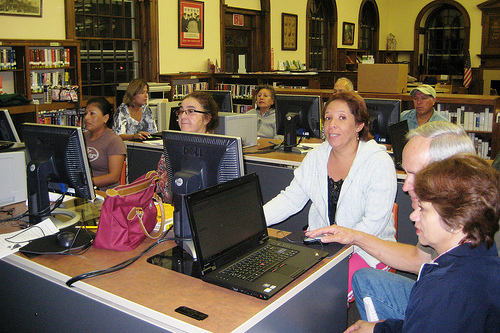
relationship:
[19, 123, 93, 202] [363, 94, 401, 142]
back of computer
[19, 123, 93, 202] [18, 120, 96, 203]
back of monitor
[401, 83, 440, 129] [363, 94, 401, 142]
man at computer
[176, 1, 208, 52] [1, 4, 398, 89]
picture on wall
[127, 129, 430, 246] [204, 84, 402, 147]
table with computers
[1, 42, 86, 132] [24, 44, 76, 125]
bookcase holding books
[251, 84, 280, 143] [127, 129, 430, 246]
lady at table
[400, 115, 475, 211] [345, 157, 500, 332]
man next to woman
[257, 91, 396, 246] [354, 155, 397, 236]
woman wears white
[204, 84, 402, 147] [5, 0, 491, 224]
computers in library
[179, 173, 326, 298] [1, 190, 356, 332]
laptop on near table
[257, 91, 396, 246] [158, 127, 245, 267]
woman in front of computer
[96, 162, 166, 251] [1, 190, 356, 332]
bag on near table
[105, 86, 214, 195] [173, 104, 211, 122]
lady wearing glasses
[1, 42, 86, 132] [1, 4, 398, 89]
bookcase against wall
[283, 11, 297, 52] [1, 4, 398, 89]
poster on wall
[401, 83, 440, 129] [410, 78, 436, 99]
man wearing cap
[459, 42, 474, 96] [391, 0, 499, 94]
flag at back wall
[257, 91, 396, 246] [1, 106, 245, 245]
woman working on computers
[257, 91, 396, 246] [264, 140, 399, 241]
woman wears jacket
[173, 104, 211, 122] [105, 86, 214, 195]
glasses on lady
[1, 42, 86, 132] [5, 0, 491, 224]
bookcase in library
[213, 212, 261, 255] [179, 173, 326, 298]
black color of laptop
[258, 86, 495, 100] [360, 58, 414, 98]
counter holds a box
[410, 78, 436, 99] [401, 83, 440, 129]
cap on man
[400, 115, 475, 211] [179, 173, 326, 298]
man using laptop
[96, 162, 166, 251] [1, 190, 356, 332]
bag on desk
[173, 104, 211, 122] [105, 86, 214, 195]
glasses on a lady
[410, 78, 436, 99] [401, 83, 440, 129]
cap worn by man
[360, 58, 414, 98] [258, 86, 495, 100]
box on counter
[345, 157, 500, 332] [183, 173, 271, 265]
woman at flatscreen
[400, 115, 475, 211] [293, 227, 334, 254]
man holding mouse